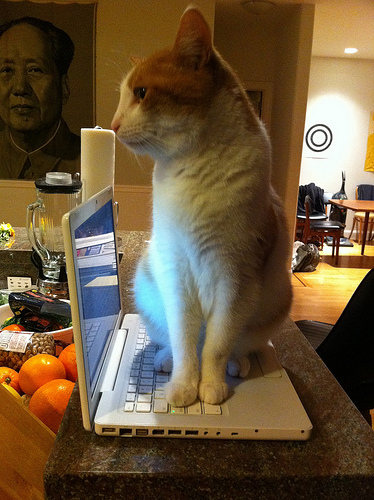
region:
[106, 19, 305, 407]
white and orange cat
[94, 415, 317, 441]
ports on side of laptop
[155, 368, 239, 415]
white paws on white keys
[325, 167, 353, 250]
vacuum behind dining room table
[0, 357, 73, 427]
bright shiny oranges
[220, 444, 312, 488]
brown granite counter top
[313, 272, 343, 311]
light stained wood floors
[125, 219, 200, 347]
reflection of light from laptop on cat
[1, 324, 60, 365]
nuts in a bag with label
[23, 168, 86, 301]
glass blender with black lid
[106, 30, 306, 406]
The cat is orange and white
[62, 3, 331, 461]
Cat is sitting on open laptop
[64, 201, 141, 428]
The laptop is white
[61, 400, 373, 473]
The laptop is on a marble counter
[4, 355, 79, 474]
Oranges are in a wooden basket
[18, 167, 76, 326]
Blender on counter top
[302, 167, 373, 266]
Kitchen table with chairs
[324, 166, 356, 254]
Vacuum behind kitchen table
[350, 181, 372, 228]
black jacket on the back of the chair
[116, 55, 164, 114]
The cat has gold eyes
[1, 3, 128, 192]
A portrait of Mao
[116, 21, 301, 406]
An orange and white cat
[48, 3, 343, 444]
A cat sitting on a laptop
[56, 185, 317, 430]
The laptop is open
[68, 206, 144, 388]
The laptop is on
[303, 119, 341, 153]
A target on the far wall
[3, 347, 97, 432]
Oranges by the laptop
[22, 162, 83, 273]
A blender behind the laptop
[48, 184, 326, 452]
A white laptop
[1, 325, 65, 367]
Beans by the oranges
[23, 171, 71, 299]
Blender sitting on counter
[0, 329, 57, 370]
Bag of nuts on counter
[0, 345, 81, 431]
Oranges on counter top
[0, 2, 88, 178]
Picture of Asian man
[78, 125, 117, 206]
Paper towels on counter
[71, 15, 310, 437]
cat sitting on laptop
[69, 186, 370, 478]
Laptop sitting on counter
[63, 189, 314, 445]
White laptop is open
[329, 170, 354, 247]
Vacuum cleaner on floor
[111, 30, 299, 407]
Cat sitting on a laptop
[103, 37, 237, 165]
Orange and white cat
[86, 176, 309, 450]
White laptop with a cat on top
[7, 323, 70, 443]
Oranges in a box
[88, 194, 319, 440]
Laptop on a counter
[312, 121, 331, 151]
Picture on a wall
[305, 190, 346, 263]
Wooden and Leather Single chair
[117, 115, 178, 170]
White whiskers on a cat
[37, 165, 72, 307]
Black blender on a table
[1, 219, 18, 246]
Piece of paper on a counter top